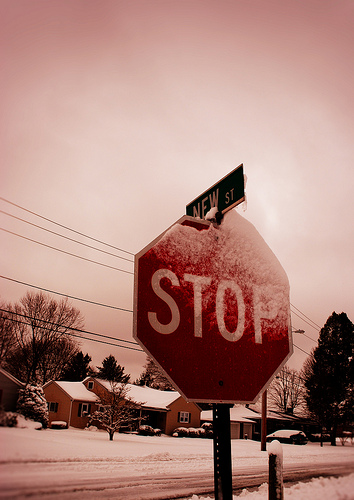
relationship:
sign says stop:
[133, 216, 292, 403] [150, 267, 279, 346]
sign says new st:
[185, 163, 245, 213] [191, 189, 234, 218]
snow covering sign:
[150, 212, 293, 328] [133, 216, 292, 403]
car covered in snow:
[269, 430, 309, 444] [271, 428, 301, 440]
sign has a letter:
[133, 216, 292, 403] [217, 281, 245, 342]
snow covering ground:
[150, 212, 293, 328] [2, 428, 353, 499]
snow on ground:
[150, 212, 293, 328] [2, 428, 353, 499]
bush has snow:
[5, 413, 19, 430] [150, 212, 293, 328]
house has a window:
[43, 374, 203, 437] [178, 409, 191, 422]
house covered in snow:
[43, 374, 203, 437] [150, 212, 293, 328]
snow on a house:
[150, 212, 293, 328] [43, 374, 203, 437]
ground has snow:
[2, 428, 353, 499] [150, 212, 293, 328]